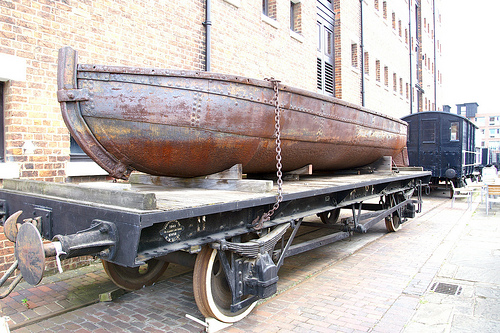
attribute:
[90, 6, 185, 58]
wall — red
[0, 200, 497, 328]
ground — brown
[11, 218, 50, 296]
disk — metal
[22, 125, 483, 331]
track — rail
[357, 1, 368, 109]
drain pipe — black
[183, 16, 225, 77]
pipes — black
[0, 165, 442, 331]
flatbed — iron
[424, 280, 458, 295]
sewer cover — meshed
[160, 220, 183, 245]
sticker — black, white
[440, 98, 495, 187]
building — tall, multi story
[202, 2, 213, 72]
pipe — black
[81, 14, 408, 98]
building — large, red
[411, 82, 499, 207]
car — old, black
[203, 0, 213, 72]
pipe — black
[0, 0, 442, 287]
wall — brick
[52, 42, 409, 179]
boat — brown, large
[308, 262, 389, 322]
floor — brown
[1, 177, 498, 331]
pavement — brick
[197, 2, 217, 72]
pipe — attached